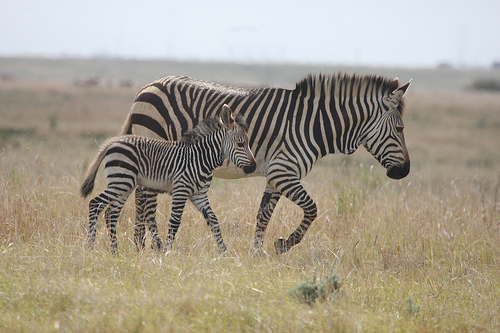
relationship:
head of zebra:
[352, 78, 423, 207] [66, 58, 411, 294]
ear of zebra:
[389, 71, 422, 105] [66, 58, 411, 294]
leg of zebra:
[160, 171, 237, 248] [66, 58, 411, 294]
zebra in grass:
[66, 58, 411, 294] [4, 78, 494, 333]